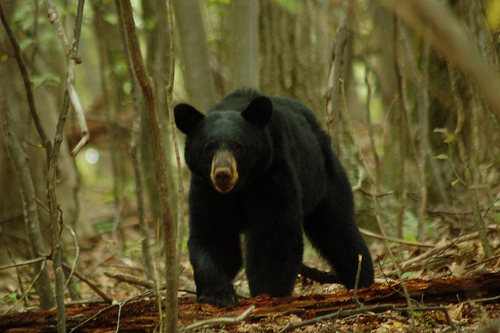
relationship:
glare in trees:
[79, 134, 106, 169] [8, 0, 496, 315]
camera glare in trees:
[68, 130, 110, 182] [8, 0, 496, 315]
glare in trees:
[79, 134, 106, 169] [196, 27, 419, 122]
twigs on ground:
[46, 234, 486, 323] [4, 217, 496, 330]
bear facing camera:
[155, 87, 388, 299] [2, 2, 496, 328]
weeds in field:
[0, 80, 194, 331] [4, 0, 496, 328]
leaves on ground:
[79, 211, 137, 264] [1, 156, 496, 331]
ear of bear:
[242, 98, 278, 122] [95, 61, 432, 318]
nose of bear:
[205, 149, 252, 196] [129, 73, 359, 262]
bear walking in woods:
[173, 87, 376, 310] [4, 3, 498, 329]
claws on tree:
[192, 287, 241, 313] [107, 287, 266, 331]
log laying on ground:
[3, 268, 498, 325] [178, 257, 484, 304]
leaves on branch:
[99, 211, 137, 260] [45, 65, 154, 236]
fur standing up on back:
[230, 85, 257, 97] [221, 80, 306, 117]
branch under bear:
[301, 263, 344, 291] [173, 87, 376, 310]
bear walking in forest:
[173, 87, 376, 310] [3, 0, 499, 331]